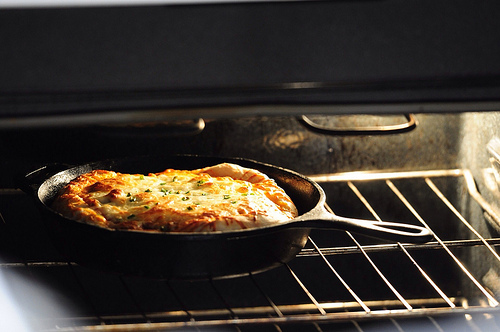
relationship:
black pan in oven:
[21, 154, 434, 282] [5, 14, 489, 329]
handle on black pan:
[290, 206, 434, 246] [21, 154, 434, 282]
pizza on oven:
[55, 164, 299, 233] [0, 98, 500, 330]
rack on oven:
[0, 159, 498, 330] [5, 14, 489, 329]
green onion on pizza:
[151, 177, 226, 207] [59, 167, 300, 230]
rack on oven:
[0, 167, 500, 332] [5, 14, 489, 329]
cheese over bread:
[57, 163, 297, 233] [49, 160, 299, 234]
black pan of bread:
[21, 154, 434, 282] [55, 162, 299, 232]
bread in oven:
[55, 162, 299, 232] [5, 14, 489, 329]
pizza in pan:
[55, 164, 299, 233] [20, 160, 436, 284]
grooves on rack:
[479, 138, 499, 295] [0, 159, 498, 330]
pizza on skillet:
[55, 164, 299, 233] [26, 154, 431, 277]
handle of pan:
[292, 208, 433, 244] [39, 139, 391, 276]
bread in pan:
[55, 162, 299, 232] [15, 114, 485, 279]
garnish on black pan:
[115, 175, 215, 227] [21, 154, 434, 282]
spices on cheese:
[105, 169, 239, 219] [95, 166, 275, 223]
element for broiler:
[292, 111, 420, 134] [298, 117, 428, 147]